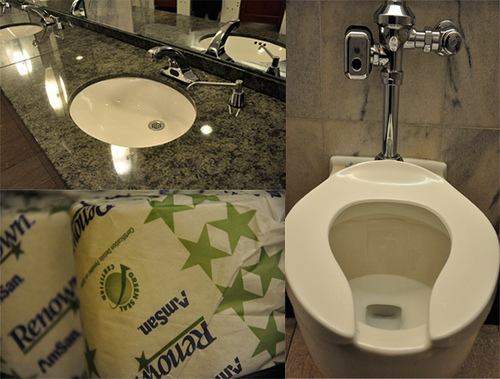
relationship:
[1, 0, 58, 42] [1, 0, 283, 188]
sink on counter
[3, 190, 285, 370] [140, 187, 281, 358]
wrapping with stars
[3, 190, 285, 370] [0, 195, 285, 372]
wrapping around rolls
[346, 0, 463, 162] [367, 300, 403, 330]
silver plumbing attaching water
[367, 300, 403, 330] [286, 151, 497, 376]
water to toilet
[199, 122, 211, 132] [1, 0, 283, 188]
light on counter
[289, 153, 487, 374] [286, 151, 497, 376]
seat over toilet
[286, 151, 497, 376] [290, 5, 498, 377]
toilet inside bathroom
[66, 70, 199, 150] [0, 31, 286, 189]
sink on counter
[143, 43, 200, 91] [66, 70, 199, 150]
faucet over sink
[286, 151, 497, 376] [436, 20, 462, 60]
toilet has lever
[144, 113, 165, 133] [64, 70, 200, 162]
drain in sink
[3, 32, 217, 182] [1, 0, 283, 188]
lighting reflection on counter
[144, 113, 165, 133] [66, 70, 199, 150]
drain in sink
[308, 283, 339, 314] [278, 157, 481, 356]
seat of toilet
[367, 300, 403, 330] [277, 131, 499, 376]
water in toilet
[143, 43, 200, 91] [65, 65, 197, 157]
faucet of sink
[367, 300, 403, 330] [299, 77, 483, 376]
water in toilet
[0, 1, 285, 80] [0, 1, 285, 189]
mirror in front of sink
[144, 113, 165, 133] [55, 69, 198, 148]
drain for sink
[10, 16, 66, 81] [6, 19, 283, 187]
reflection of marble countertop